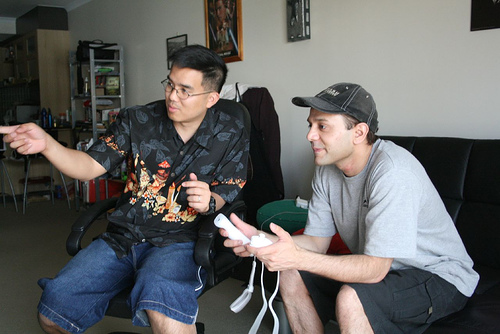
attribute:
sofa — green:
[329, 135, 496, 331]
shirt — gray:
[303, 137, 480, 298]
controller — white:
[212, 212, 271, 249]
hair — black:
[163, 39, 230, 96]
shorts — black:
[294, 247, 476, 330]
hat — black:
[290, 82, 378, 129]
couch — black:
[370, 136, 499, 330]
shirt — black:
[83, 95, 254, 257]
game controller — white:
[248, 232, 272, 252]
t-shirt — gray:
[297, 149, 482, 289]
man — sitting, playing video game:
[0, 44, 252, 332]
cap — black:
[287, 67, 375, 126]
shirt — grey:
[282, 140, 489, 317]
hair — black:
[172, 45, 229, 95]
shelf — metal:
[61, 35, 128, 153]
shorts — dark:
[290, 251, 468, 331]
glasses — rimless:
[161, 71, 215, 98]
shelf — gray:
[65, 38, 127, 144]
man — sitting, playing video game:
[228, 79, 482, 331]